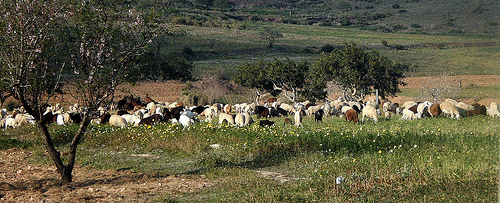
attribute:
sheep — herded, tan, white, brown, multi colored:
[2, 92, 499, 123]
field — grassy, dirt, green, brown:
[1, 31, 500, 197]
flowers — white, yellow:
[19, 117, 461, 152]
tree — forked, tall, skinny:
[11, 4, 150, 175]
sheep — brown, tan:
[344, 108, 358, 122]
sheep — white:
[360, 108, 383, 121]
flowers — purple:
[3, 5, 139, 91]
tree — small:
[261, 21, 286, 47]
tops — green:
[235, 45, 401, 87]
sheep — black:
[314, 110, 325, 122]